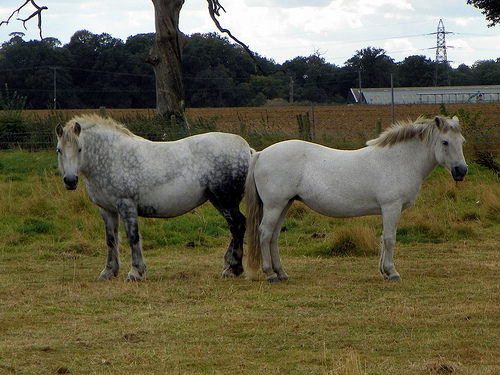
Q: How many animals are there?
A: Two.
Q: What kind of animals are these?
A: Horses.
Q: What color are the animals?
A: White.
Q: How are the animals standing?
A: Tail to tail.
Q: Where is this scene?
A: A farm.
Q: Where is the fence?
A: Under the tree.